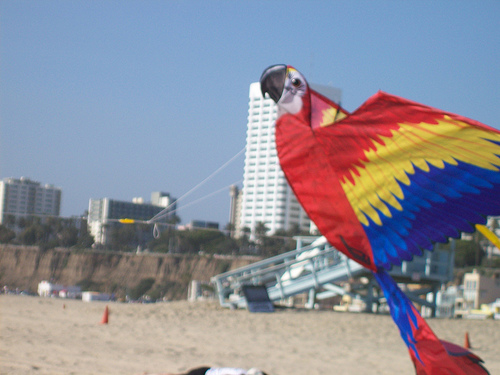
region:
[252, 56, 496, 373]
a red, blue, and yellow parrot kite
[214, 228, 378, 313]
a pale blue ramp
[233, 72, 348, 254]
a tall white building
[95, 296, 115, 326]
an orange cone in the sand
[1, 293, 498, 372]
an expanse of sand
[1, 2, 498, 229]
a beautiful blue sky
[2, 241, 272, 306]
a dirty concrete wall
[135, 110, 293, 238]
the white strings of a kite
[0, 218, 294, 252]
a fence above a concrete wall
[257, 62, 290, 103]
the black beak on a parrot kite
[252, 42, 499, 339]
Kite made to look like a parrot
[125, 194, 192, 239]
Strings of kite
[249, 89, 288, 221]
Tall white building with many windows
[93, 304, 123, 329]
Orange safety cone in sand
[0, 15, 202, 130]
Blue sky with no clouds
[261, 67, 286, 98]
Beak of kite made to look like a parrot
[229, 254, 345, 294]
Ramp leading to sandy beach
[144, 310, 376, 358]
Sand with no people or water nearby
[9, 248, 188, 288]
Steep brown cliff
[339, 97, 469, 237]
Colorful wing of kite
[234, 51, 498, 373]
A kite in the shape of a bird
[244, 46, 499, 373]
The kite is red, blue and yellow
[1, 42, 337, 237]
Buildings are in the background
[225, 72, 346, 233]
Building in the background is white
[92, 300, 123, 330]
An orange cone on the beach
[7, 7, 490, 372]
Photo was taken in the daytime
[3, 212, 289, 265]
Trees are in the background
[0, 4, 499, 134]
The sky is cloudy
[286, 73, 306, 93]
bird's eye is brown in color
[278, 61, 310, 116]
Bird's face is white in color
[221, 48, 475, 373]
Colorful parrot kite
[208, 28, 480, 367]
Kite with red, yellow, blue and purple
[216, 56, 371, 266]
Tall white building in the background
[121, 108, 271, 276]
Strings going to kite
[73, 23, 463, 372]
Flying a kite at the beach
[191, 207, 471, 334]
Walkway down to the beach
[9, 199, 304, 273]
A row of shrubbery along the fence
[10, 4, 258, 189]
A cloudless sky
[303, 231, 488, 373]
Long tail on kite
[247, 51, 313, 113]
Parrot beak and eye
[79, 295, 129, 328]
red cone on the sand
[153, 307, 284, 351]
dirt on the sand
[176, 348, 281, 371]
person laying on the sand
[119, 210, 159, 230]
yellow object on top of building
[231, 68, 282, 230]
tall white skyscraper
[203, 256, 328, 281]
hand rail on blue steps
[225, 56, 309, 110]
black beak on colorful kite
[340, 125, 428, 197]
yellow tails on the kite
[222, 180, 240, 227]
thin black building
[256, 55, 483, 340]
colorful kite with red and yellow color